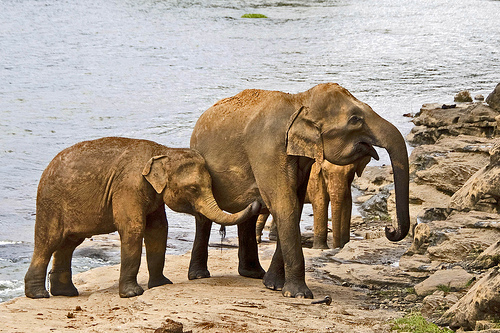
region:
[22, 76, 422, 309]
three elephants on water's edge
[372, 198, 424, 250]
curled end of trunk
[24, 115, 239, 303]
young elephant next to adult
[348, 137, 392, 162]
open mouth of elephant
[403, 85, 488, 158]
rocks on water's edge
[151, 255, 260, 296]
elephant feet on incline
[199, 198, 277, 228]
upturned trunk on elephant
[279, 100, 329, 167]
ear on adult elephant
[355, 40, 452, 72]
light reflection on water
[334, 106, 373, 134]
eye on elephant face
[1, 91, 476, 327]
A rocky shore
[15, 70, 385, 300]
A trio of elephants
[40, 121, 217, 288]
A younger elephant reaching for its mother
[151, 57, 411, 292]
an adult elephant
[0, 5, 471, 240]
A large body of water behind the elephants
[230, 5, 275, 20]
a small grass patch in the water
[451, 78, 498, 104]
some rocks sticking up from the water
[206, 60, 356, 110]
a significant amount of dirt on the adult elephant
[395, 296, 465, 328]
some grass on the rocky shore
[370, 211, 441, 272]
puddles on the shore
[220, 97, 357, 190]
this is an elephant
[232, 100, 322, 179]
the elephant is big in size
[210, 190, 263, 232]
the trunk is in front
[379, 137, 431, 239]
the trunk is long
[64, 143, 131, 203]
the back is brown in color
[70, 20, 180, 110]
water us behind the elephant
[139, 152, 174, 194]
the ear is small in size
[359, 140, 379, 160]
the mouth is open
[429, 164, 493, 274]
rocks are in front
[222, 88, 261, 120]
the back is muddy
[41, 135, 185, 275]
this is an elephant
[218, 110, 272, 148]
the elephant is brown in color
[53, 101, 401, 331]
they are two elephants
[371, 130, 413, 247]
this is a trunk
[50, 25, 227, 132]
this is a water body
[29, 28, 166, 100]
the water is calm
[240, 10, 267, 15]
this is a water weed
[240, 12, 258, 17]
thew leaves are green in color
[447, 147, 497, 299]
this is a rock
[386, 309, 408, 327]
this is a grass area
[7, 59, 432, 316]
Three elephants on the shore.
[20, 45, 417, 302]
The elephants are dirty.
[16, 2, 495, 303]
Running water along the shore.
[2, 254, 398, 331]
The ground is brown.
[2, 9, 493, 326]
Photo taken during the day.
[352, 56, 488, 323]
Rocks along the coast.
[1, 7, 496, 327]
No people shown.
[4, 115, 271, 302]
The closest elephant is young.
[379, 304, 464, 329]
Small tuft of grass.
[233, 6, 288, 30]
Mossy rock sticking out of the water.